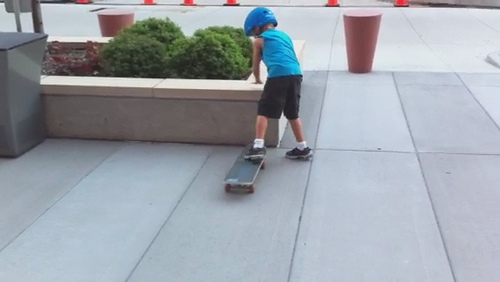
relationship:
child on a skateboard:
[243, 7, 312, 163] [222, 149, 266, 193]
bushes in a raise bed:
[100, 19, 252, 80] [45, 40, 109, 76]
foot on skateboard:
[244, 111, 268, 161] [222, 149, 266, 193]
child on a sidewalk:
[243, 7, 312, 163] [0, 1, 499, 72]